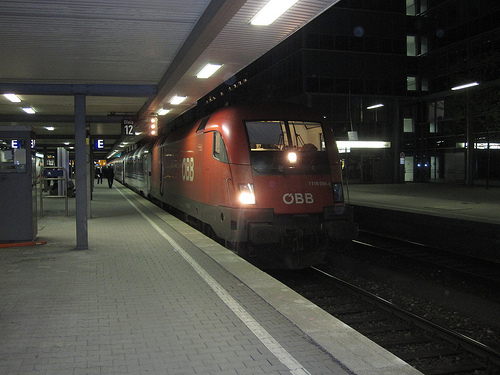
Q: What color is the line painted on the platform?
A: White.